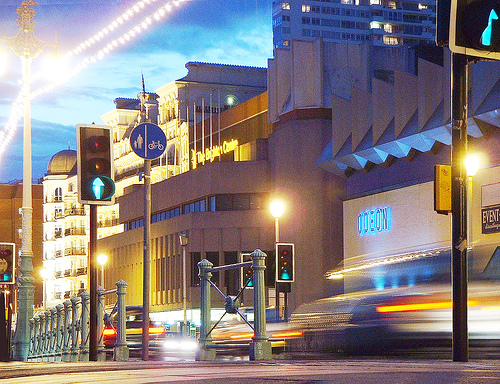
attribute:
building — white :
[271, 1, 440, 55]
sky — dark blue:
[0, 1, 271, 183]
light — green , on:
[88, 178, 115, 200]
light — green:
[275, 241, 295, 282]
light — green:
[239, 251, 252, 287]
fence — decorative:
[195, 248, 272, 366]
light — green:
[79, 125, 116, 203]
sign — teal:
[355, 205, 393, 236]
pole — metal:
[451, 49, 469, 362]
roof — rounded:
[44, 147, 79, 178]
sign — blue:
[127, 121, 167, 161]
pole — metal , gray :
[140, 159, 150, 362]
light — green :
[0, 241, 17, 283]